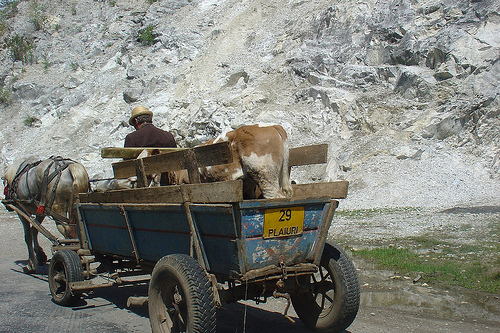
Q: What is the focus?
A: Makeshift cart in mountains.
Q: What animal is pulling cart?
A: Horse.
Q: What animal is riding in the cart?
A: Cow.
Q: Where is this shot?
A: Mountains.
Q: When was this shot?
A: Daytime.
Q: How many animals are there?
A: 2.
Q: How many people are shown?
A: 1.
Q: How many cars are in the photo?
A: 0.